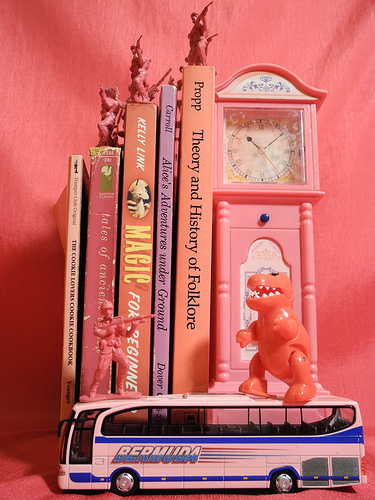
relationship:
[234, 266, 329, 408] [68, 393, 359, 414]
tyrannosaurus rex on roof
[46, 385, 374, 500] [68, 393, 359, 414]
tour bus has roof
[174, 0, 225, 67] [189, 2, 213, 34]
toy soldier has gun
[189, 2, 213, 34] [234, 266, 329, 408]
gun pointed at tyrannosaurus rex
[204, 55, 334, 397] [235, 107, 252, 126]
grandfather clock has scratch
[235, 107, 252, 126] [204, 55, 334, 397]
scratch on face of grandfather clock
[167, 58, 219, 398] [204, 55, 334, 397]
book leaning toward grandfather clock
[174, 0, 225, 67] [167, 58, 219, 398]
toy soldier on top of book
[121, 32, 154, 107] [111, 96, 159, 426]
toy soldier on top of book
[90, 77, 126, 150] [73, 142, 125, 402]
toy soldier on top of book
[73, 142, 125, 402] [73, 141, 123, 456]
book has cover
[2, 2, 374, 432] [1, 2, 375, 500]
wall in wall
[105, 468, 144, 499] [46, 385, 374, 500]
wheel on tour bus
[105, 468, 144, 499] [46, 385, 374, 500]
wheel on front of tour bus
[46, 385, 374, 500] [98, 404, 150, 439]
tour bus has window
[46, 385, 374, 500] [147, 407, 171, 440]
tour bus has window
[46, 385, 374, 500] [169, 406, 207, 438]
tour bus has window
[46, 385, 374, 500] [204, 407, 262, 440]
tour bus has window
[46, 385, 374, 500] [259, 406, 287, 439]
tour bus has window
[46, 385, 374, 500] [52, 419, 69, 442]
tour bus has rear view mirror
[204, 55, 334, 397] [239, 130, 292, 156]
grandfather clock has hands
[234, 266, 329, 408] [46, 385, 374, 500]
tyrannosaurus rex standing on tour bus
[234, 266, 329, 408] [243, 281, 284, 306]
tyrannosaurus rex has teeth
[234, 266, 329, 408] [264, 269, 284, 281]
tyrannosaurus rex has eye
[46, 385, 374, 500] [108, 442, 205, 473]
tour bus has writing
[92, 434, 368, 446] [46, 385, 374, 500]
line on side of tour bus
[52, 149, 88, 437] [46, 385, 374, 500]
book behind tour bus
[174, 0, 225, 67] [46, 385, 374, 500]
toy soldier on top of tour bus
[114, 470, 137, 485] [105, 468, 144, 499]
part of wheel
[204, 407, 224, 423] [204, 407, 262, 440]
part of window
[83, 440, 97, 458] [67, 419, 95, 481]
part of door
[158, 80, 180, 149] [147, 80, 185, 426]
part of book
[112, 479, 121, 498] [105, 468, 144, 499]
edge of wheel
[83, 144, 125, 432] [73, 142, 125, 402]
side of book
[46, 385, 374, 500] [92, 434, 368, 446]
tour bus has line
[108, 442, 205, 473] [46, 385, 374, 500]
writing on side of tour bus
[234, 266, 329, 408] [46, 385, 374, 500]
tyrannosaurus rex on top of tour bus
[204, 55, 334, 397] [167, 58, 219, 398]
grandfather clock next to book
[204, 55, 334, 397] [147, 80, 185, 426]
grandfather clock next to book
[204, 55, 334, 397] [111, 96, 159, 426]
grandfather clock next to book